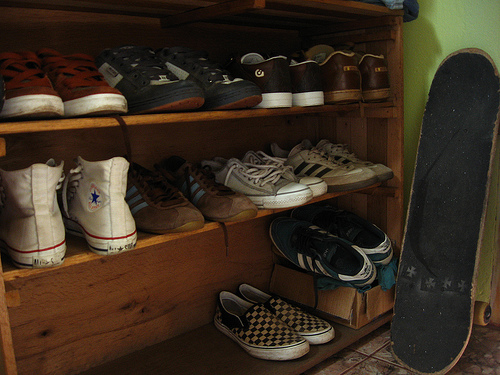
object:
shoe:
[98, 45, 206, 115]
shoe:
[269, 217, 382, 290]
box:
[269, 263, 396, 327]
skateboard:
[395, 47, 497, 371]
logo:
[91, 191, 102, 206]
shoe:
[63, 158, 140, 254]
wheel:
[472, 300, 492, 331]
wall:
[398, 2, 497, 326]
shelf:
[1, 0, 402, 374]